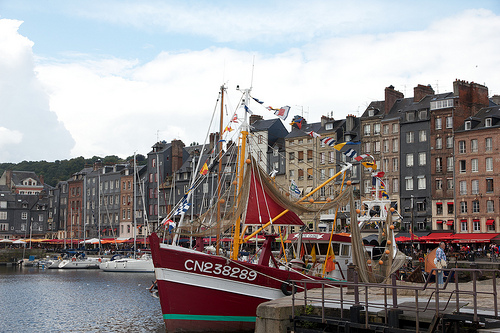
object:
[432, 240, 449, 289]
person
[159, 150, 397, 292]
rope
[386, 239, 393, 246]
balls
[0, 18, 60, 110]
cloud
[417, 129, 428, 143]
window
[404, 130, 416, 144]
window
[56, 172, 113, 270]
boat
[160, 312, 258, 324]
stripe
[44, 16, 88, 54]
patch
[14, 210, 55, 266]
boats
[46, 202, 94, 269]
boats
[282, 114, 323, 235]
buildings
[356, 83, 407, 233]
buildings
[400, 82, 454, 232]
buildings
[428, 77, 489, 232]
buildings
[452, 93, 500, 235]
buildings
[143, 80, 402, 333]
boat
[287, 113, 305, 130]
pennants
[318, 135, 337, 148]
pennants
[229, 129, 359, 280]
rigging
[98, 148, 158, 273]
white boat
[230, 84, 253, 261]
mast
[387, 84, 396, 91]
chimney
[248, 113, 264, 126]
chimney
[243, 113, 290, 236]
building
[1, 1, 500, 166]
sky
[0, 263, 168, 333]
water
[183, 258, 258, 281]
identification number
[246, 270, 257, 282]
number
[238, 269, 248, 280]
number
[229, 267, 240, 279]
number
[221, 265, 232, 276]
number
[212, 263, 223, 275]
number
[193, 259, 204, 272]
letter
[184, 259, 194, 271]
letter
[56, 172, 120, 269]
boat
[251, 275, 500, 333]
dock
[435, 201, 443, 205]
red awnings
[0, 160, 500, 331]
harbor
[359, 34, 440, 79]
clouds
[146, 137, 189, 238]
buildings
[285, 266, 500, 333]
pier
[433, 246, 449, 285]
outfit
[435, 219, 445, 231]
window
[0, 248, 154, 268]
dock